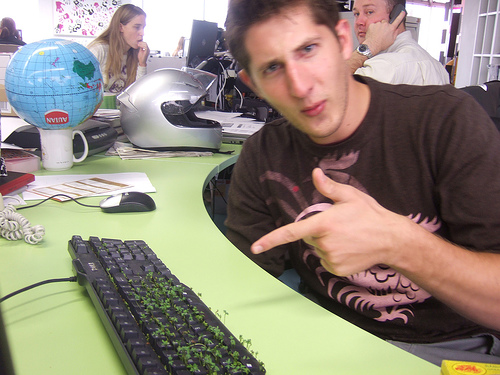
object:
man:
[217, 2, 500, 368]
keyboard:
[64, 236, 263, 375]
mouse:
[100, 190, 156, 213]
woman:
[85, 7, 147, 103]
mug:
[38, 127, 89, 172]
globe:
[3, 40, 106, 124]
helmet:
[115, 66, 222, 153]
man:
[348, 1, 450, 88]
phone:
[387, 4, 408, 30]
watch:
[355, 44, 372, 58]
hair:
[225, 0, 344, 88]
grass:
[132, 269, 256, 373]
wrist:
[353, 38, 376, 58]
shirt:
[353, 30, 447, 87]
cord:
[3, 193, 48, 245]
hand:
[250, 167, 394, 276]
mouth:
[137, 39, 143, 44]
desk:
[3, 144, 444, 375]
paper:
[21, 169, 157, 205]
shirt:
[221, 80, 500, 345]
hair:
[88, 3, 147, 90]